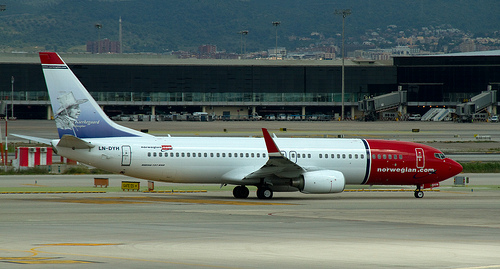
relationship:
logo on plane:
[375, 164, 435, 175] [10, 51, 461, 196]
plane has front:
[10, 51, 461, 196] [369, 140, 465, 187]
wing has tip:
[244, 127, 307, 183] [262, 126, 281, 153]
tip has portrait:
[37, 52, 134, 139] [52, 92, 91, 138]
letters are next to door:
[95, 144, 123, 152] [122, 143, 132, 169]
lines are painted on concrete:
[56, 195, 294, 208] [0, 186, 496, 269]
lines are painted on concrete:
[0, 238, 120, 268] [0, 186, 496, 269]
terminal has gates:
[0, 50, 498, 119] [402, 82, 445, 106]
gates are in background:
[402, 82, 445, 106] [361, 37, 497, 126]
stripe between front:
[362, 138, 372, 185] [369, 140, 465, 187]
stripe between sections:
[362, 138, 372, 185] [52, 135, 365, 183]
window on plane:
[147, 151, 152, 159] [10, 51, 461, 196]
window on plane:
[155, 152, 159, 159] [10, 51, 461, 196]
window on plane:
[158, 152, 165, 158] [10, 51, 461, 196]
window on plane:
[164, 152, 170, 159] [10, 51, 461, 196]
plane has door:
[10, 51, 461, 196] [122, 143, 132, 169]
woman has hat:
[52, 92, 91, 138] [56, 91, 88, 118]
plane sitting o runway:
[10, 51, 461, 196] [0, 186, 496, 269]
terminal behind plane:
[0, 50, 498, 119] [10, 51, 461, 196]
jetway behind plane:
[356, 86, 410, 117] [10, 51, 461, 196]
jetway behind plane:
[458, 87, 498, 116] [10, 51, 461, 196]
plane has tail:
[10, 51, 461, 196] [37, 52, 134, 139]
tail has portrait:
[37, 52, 134, 139] [52, 92, 91, 138]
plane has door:
[10, 51, 461, 196] [291, 150, 298, 165]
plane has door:
[10, 51, 461, 196] [281, 150, 288, 160]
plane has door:
[10, 51, 461, 196] [416, 150, 425, 169]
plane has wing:
[10, 51, 461, 196] [244, 127, 307, 183]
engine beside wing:
[292, 169, 345, 197] [244, 127, 307, 183]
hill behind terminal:
[2, 3, 498, 53] [0, 50, 498, 119]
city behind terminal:
[87, 24, 499, 62] [0, 50, 498, 119]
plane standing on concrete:
[10, 51, 461, 196] [0, 186, 496, 269]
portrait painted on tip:
[52, 92, 91, 138] [37, 52, 134, 139]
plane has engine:
[10, 51, 461, 196] [292, 169, 345, 197]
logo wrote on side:
[375, 164, 435, 175] [375, 157, 459, 183]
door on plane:
[122, 143, 132, 169] [10, 51, 461, 196]